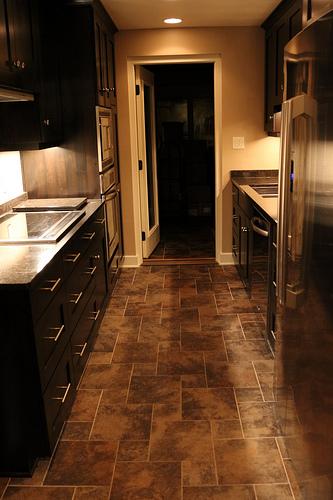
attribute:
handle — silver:
[39, 267, 65, 299]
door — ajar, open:
[130, 63, 172, 258]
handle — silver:
[248, 216, 269, 239]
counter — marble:
[2, 183, 115, 290]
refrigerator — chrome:
[274, 10, 332, 489]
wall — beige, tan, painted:
[115, 27, 283, 283]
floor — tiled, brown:
[72, 261, 290, 497]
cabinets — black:
[2, 3, 75, 153]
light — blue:
[282, 164, 302, 188]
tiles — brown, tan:
[134, 269, 220, 323]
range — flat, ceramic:
[2, 203, 88, 248]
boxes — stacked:
[178, 138, 214, 220]